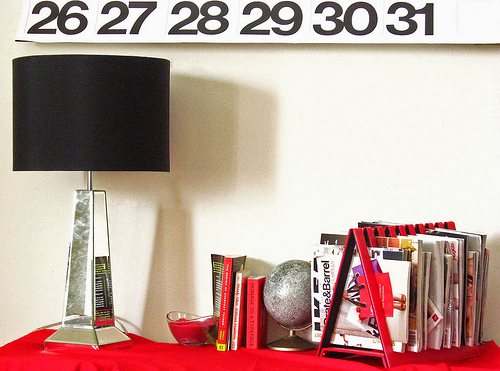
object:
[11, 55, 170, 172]
blackshade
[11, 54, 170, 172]
lampshade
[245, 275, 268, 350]
book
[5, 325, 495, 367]
red cloth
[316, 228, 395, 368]
triangle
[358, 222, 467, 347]
magazine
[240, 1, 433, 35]
numbers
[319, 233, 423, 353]
book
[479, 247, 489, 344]
magazine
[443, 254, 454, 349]
magazine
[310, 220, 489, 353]
magazine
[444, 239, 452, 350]
magazine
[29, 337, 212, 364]
surface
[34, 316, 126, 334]
cord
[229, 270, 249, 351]
book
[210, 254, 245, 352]
book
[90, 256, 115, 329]
book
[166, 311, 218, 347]
candle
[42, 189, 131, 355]
base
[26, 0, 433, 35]
numbers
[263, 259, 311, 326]
sphere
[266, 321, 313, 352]
holder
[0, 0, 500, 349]
wall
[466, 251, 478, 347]
magazine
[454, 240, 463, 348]
magazine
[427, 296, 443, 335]
magazine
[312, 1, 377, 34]
number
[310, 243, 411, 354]
book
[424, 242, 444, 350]
book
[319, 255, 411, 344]
book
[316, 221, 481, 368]
magazine rack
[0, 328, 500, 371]
cloth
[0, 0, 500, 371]
photo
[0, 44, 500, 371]
items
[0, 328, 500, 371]
table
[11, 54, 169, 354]
lamp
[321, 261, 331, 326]
writing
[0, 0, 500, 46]
background